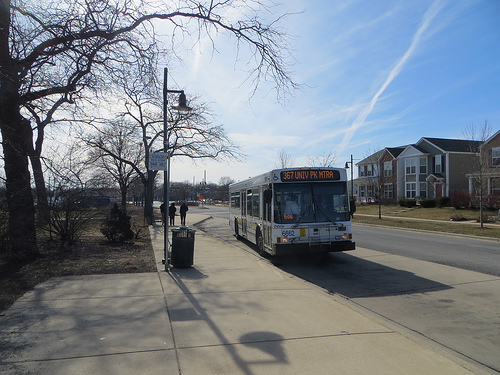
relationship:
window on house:
[433, 154, 442, 175] [397, 137, 486, 208]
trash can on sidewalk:
[171, 224, 196, 269] [1, 212, 494, 374]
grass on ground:
[1, 200, 498, 316] [1, 199, 500, 374]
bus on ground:
[228, 166, 357, 264] [1, 199, 500, 374]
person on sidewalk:
[168, 202, 177, 227] [1, 212, 494, 374]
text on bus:
[281, 169, 334, 180] [228, 166, 357, 264]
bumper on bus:
[274, 241, 357, 255] [228, 166, 357, 264]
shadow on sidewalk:
[0, 223, 290, 372] [1, 212, 494, 374]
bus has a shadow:
[228, 166, 357, 264] [234, 227, 457, 300]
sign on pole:
[148, 151, 169, 172] [160, 151, 171, 272]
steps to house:
[391, 203, 422, 215] [397, 137, 486, 208]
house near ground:
[397, 137, 486, 208] [1, 199, 500, 374]